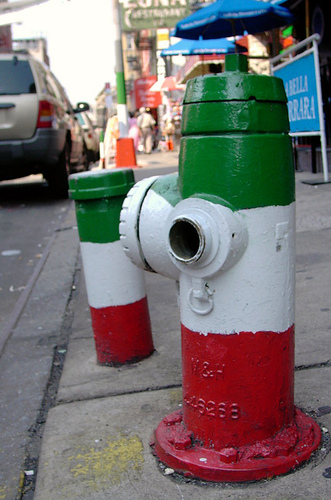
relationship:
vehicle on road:
[0, 49, 88, 191] [6, 170, 71, 498]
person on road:
[136, 100, 159, 158] [6, 170, 71, 498]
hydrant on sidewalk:
[126, 41, 330, 468] [63, 127, 326, 499]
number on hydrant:
[230, 402, 239, 422] [126, 41, 330, 468]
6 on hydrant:
[218, 400, 230, 421] [126, 41, 330, 468]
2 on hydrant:
[205, 399, 217, 422] [126, 41, 330, 468]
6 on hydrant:
[196, 397, 205, 417] [126, 41, 330, 468]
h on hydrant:
[212, 363, 228, 384] [126, 41, 330, 468]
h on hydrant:
[188, 357, 200, 380] [126, 41, 330, 468]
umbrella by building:
[176, 3, 285, 36] [262, 5, 327, 171]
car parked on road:
[75, 102, 110, 163] [6, 170, 71, 498]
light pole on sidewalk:
[110, 7, 131, 156] [63, 127, 326, 499]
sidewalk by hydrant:
[63, 127, 326, 499] [126, 41, 330, 468]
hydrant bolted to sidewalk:
[126, 41, 330, 468] [63, 127, 326, 499]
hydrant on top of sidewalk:
[126, 41, 330, 468] [63, 127, 326, 499]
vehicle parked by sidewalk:
[0, 49, 88, 191] [63, 127, 326, 499]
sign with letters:
[133, 77, 158, 110] [135, 80, 160, 105]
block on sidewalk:
[110, 139, 141, 168] [63, 127, 326, 499]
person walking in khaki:
[136, 100, 159, 158] [141, 130, 154, 149]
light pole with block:
[110, 7, 131, 156] [110, 139, 141, 168]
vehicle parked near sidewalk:
[0, 49, 88, 191] [63, 127, 326, 499]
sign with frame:
[270, 36, 322, 144] [257, 37, 327, 177]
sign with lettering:
[270, 36, 322, 144] [284, 74, 311, 119]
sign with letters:
[114, 1, 240, 30] [123, 2, 202, 29]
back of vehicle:
[4, 54, 45, 166] [0, 49, 88, 191]